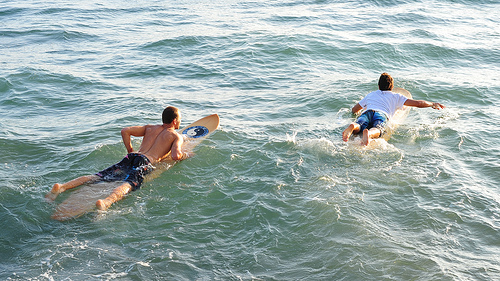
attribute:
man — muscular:
[43, 95, 192, 220]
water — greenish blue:
[0, 1, 499, 278]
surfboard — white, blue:
[65, 114, 225, 224]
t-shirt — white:
[357, 89, 406, 118]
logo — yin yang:
[188, 123, 204, 137]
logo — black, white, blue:
[185, 107, 210, 143]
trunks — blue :
[352, 107, 388, 136]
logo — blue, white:
[183, 122, 207, 137]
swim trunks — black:
[97, 151, 157, 191]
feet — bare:
[48, 180, 106, 218]